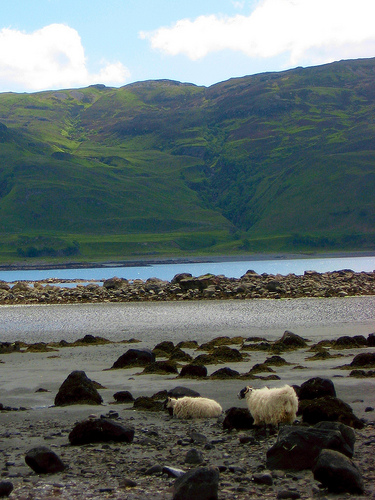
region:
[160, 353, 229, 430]
White animal near rocks.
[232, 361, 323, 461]
White animal near rocks.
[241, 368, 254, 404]
Horns on animal's head.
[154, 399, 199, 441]
Horns on animals head.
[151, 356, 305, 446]
2 white animals on beach area.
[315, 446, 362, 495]
Large dark rock on beach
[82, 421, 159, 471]
Large dark rock on beach.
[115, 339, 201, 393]
Large rocks on beach area.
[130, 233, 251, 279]
Blue water in distance.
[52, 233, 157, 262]
Grassy area behind water.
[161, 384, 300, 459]
wild sheep on the shoreline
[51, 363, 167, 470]
rocks and sand on the shoreline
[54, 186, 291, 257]
beautiful green hills in the background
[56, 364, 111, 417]
rocks and sand on the shore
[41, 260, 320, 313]
a rocky beach in the background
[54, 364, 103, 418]
large boulder rocks on the beach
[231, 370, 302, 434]
wooley sheep standing in the sand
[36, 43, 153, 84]
cloudy blue sky in the distance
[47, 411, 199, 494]
peebles and rocks in the sand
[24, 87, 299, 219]
beautiful mountain side in the distance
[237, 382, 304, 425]
a white sheep standing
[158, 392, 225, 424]
a white sheep sitting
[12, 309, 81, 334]
a portion of water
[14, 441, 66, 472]
a large rock on dirt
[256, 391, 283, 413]
portion of lamb's fur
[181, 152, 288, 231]
an indented portion of green area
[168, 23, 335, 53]
clouds in the sky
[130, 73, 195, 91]
top part of mountain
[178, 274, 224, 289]
a large boulder rock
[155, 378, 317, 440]
2 sheep on land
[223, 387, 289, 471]
the sheep is white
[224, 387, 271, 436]
the sheep is white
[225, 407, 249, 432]
the sheep is white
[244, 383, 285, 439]
the sheep is white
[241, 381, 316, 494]
the sheep is white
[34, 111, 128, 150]
sunlight casting on the mountain side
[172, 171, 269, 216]
dips in the valley floor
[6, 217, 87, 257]
small green trees on the ground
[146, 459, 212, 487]
small black bottle on the sand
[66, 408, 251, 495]
big black boulders on the sand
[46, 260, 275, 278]
tranquil blue waters in the lake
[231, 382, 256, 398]
black head on white sheep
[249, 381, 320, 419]
large area of white wool on sheep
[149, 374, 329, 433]
sheeps among the rocks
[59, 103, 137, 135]
bare area on mountain side